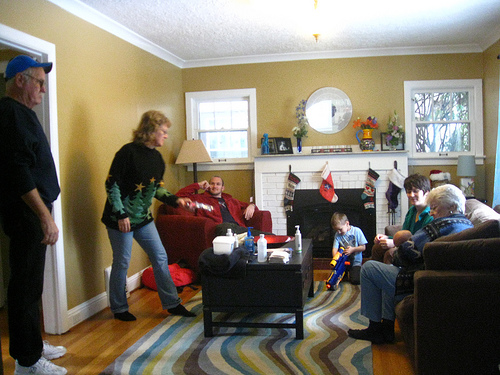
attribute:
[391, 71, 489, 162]
frame — white 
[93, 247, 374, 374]
carpet — blue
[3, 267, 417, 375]
floor — wooden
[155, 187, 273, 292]
chair — red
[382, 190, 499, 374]
couch — brown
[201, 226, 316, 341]
table — black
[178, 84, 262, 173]
window — white , circle, square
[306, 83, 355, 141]
window — circle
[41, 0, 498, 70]
ceiling — white